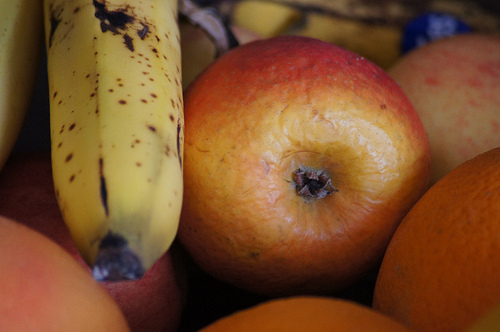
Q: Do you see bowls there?
A: No, there are no bowls.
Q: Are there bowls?
A: No, there are no bowls.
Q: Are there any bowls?
A: No, there are no bowls.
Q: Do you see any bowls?
A: No, there are no bowls.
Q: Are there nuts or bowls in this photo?
A: No, there are no bowls or nuts.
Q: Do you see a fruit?
A: Yes, there is a fruit.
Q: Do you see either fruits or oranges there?
A: Yes, there is a fruit.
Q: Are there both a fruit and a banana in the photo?
A: Yes, there are both a fruit and a banana.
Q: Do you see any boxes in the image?
A: No, there are no boxes.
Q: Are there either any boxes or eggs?
A: No, there are no boxes or eggs.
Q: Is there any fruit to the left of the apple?
A: Yes, there is a fruit to the left of the apple.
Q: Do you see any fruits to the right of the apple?
A: No, the fruit is to the left of the apple.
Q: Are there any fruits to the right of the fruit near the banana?
A: No, the fruit is to the left of the apple.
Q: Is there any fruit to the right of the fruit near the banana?
A: No, the fruit is to the left of the apple.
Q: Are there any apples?
A: Yes, there is an apple.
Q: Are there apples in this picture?
A: Yes, there is an apple.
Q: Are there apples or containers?
A: Yes, there is an apple.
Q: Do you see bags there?
A: No, there are no bags.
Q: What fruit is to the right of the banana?
A: The fruit is an apple.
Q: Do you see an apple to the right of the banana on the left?
A: Yes, there is an apple to the right of the banana.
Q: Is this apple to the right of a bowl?
A: No, the apple is to the right of the banana.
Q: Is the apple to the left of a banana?
A: No, the apple is to the right of a banana.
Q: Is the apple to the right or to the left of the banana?
A: The apple is to the right of the banana.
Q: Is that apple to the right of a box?
A: No, the apple is to the right of a fruit.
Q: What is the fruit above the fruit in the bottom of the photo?
A: The fruit is an apple.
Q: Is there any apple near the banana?
A: Yes, there is an apple near the banana.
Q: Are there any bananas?
A: Yes, there is a banana.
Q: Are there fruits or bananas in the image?
A: Yes, there is a banana.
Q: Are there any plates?
A: No, there are no plates.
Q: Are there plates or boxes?
A: No, there are no plates or boxes.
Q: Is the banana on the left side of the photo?
A: Yes, the banana is on the left of the image.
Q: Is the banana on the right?
A: No, the banana is on the left of the image.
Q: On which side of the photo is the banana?
A: The banana is on the left of the image.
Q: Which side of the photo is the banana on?
A: The banana is on the left of the image.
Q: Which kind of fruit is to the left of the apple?
A: The fruit is a banana.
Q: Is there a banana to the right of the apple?
A: No, the banana is to the left of the apple.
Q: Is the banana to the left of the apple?
A: Yes, the banana is to the left of the apple.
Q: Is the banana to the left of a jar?
A: No, the banana is to the left of the apple.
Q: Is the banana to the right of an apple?
A: No, the banana is to the left of an apple.